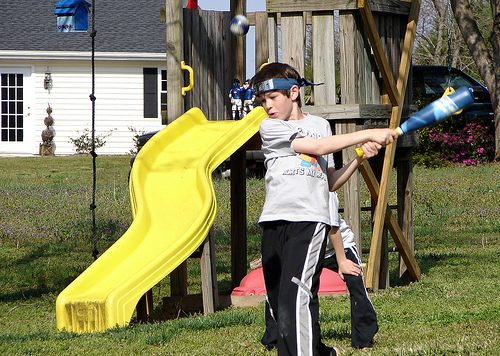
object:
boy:
[250, 61, 332, 353]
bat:
[355, 85, 474, 160]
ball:
[228, 12, 252, 37]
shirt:
[256, 112, 336, 227]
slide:
[52, 105, 271, 328]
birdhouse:
[53, 1, 94, 34]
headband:
[251, 76, 325, 94]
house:
[1, 1, 170, 159]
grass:
[1, 156, 499, 356]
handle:
[353, 127, 404, 158]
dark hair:
[248, 61, 302, 109]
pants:
[260, 217, 331, 355]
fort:
[263, 1, 423, 293]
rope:
[86, 1, 104, 262]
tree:
[39, 101, 59, 158]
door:
[1, 63, 37, 160]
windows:
[139, 73, 165, 116]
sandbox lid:
[228, 261, 354, 307]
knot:
[87, 25, 101, 40]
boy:
[325, 189, 377, 350]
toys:
[225, 78, 256, 122]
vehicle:
[413, 59, 499, 133]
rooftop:
[1, 1, 168, 54]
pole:
[165, 2, 185, 131]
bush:
[417, 119, 497, 173]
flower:
[475, 146, 485, 157]